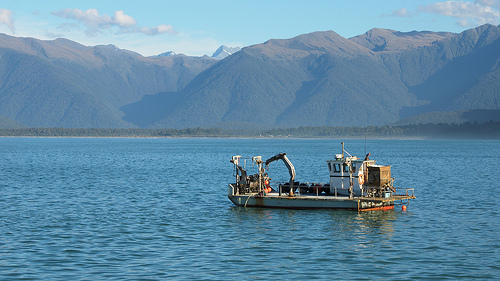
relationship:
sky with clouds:
[46, 5, 216, 35] [48, 11, 172, 41]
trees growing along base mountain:
[3, 117, 498, 139] [3, 21, 492, 116]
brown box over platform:
[363, 165, 393, 186] [363, 187, 413, 202]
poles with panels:
[232, 154, 264, 194] [237, 164, 257, 191]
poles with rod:
[232, 154, 264, 194] [227, 150, 264, 196]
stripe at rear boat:
[355, 205, 396, 212] [226, 142, 416, 212]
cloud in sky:
[0, 0, 498, 42] [2, 3, 497, 60]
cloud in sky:
[0, 0, 498, 42] [4, 2, 498, 54]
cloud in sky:
[0, 0, 498, 42] [191, 10, 261, 29]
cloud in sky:
[381, 0, 497, 27] [4, 2, 498, 54]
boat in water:
[226, 142, 416, 212] [5, 135, 498, 274]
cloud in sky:
[0, 0, 498, 42] [132, 4, 371, 60]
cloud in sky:
[0, 0, 498, 42] [97, 4, 465, 57]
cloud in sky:
[0, 0, 498, 42] [162, 2, 331, 23]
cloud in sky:
[0, 0, 498, 42] [74, 10, 174, 39]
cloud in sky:
[0, 0, 498, 42] [165, 6, 227, 43]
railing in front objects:
[281, 180, 356, 189] [323, 185, 328, 193]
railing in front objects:
[281, 180, 356, 189] [308, 182, 317, 197]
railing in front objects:
[281, 180, 356, 189] [300, 182, 307, 191]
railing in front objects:
[281, 180, 356, 189] [281, 182, 296, 190]